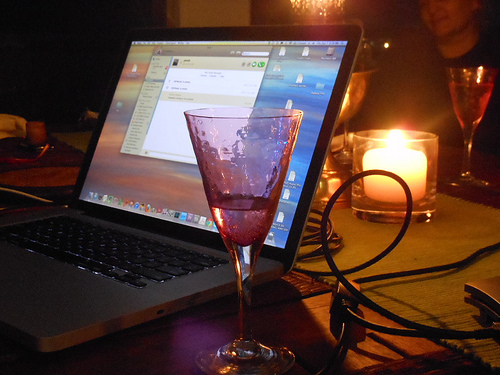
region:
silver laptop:
[1, 14, 338, 371]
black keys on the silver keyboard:
[13, 203, 218, 302]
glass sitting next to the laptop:
[180, 96, 316, 373]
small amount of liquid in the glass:
[209, 188, 265, 253]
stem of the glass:
[199, 243, 294, 374]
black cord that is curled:
[286, 155, 498, 357]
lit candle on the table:
[347, 122, 438, 226]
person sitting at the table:
[386, 2, 497, 180]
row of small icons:
[85, 188, 270, 244]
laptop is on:
[0, 10, 365, 350]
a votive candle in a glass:
[348, 129, 436, 222]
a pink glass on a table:
[185, 107, 304, 374]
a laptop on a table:
[0, 23, 364, 353]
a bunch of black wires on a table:
[289, 167, 495, 374]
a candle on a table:
[23, 120, 45, 145]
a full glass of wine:
[444, 65, 493, 189]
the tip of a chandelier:
[291, 0, 344, 19]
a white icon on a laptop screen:
[277, 47, 287, 57]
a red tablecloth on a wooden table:
[0, 128, 494, 373]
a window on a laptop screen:
[119, 46, 273, 166]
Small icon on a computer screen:
[312, 39, 342, 69]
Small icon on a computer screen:
[295, 41, 313, 63]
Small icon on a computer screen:
[265, 38, 295, 62]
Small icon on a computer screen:
[265, 61, 295, 83]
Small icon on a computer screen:
[290, 65, 310, 90]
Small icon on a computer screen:
[308, 77, 330, 99]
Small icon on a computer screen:
[273, 95, 303, 112]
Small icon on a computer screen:
[283, 163, 307, 187]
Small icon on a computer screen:
[275, 186, 300, 203]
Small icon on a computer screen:
[269, 205, 292, 232]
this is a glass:
[155, 92, 309, 373]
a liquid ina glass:
[207, 199, 271, 257]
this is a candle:
[344, 89, 448, 261]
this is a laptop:
[10, 35, 352, 359]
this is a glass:
[444, 48, 491, 208]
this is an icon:
[275, 63, 329, 104]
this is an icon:
[264, 91, 299, 133]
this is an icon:
[265, 38, 292, 68]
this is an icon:
[282, 71, 309, 101]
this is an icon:
[264, 198, 291, 232]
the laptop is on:
[138, 73, 177, 120]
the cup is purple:
[223, 151, 258, 191]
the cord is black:
[332, 251, 359, 280]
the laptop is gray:
[46, 280, 83, 308]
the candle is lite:
[378, 121, 413, 153]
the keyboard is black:
[81, 231, 121, 261]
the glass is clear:
[414, 201, 436, 220]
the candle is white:
[413, 188, 428, 200]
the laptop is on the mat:
[259, 266, 296, 291]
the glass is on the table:
[185, 346, 227, 372]